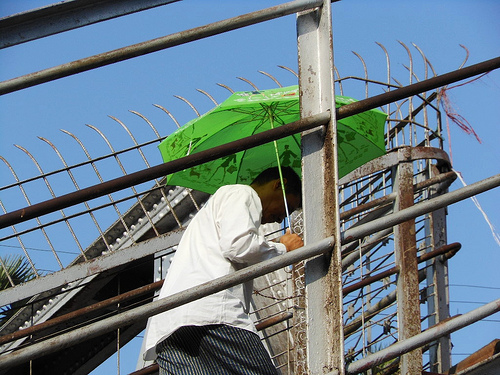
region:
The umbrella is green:
[187, 78, 287, 182]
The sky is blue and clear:
[74, 14, 204, 129]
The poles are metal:
[316, 94, 438, 301]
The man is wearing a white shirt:
[150, 181, 294, 368]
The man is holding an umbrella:
[253, 150, 320, 287]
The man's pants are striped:
[174, 322, 241, 373]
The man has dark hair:
[239, 158, 320, 248]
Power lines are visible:
[433, 182, 496, 339]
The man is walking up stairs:
[90, 155, 311, 357]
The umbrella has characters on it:
[181, 114, 370, 230]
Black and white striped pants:
[155, 319, 285, 374]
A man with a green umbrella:
[159, 81, 390, 198]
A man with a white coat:
[140, 179, 291, 363]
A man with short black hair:
[255, 162, 307, 210]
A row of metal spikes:
[0, 35, 471, 292]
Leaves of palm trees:
[0, 252, 54, 330]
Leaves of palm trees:
[346, 340, 446, 374]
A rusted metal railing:
[0, 144, 462, 374]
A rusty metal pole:
[0, 55, 498, 233]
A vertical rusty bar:
[295, 2, 347, 374]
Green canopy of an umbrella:
[158, 85, 383, 204]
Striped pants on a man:
[154, 320, 281, 372]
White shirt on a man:
[141, 185, 282, 334]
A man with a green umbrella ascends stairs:
[143, 85, 397, 373]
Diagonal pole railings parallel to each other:
[3, 10, 498, 373]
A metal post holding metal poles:
[390, 153, 423, 374]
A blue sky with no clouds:
[2, 4, 498, 322]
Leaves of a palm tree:
[0, 255, 62, 304]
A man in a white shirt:
[141, 165, 306, 373]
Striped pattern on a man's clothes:
[165, 343, 261, 373]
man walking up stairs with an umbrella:
[135, 87, 389, 374]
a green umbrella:
[160, 87, 389, 249]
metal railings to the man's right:
[1, 6, 498, 373]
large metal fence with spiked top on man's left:
[0, 44, 448, 374]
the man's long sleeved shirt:
[142, 184, 302, 357]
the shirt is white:
[131, 183, 287, 355]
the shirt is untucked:
[144, 181, 291, 360]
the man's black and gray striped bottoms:
[158, 325, 280, 373]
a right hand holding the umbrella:
[279, 230, 304, 255]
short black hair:
[251, 167, 301, 203]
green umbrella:
[148, 76, 385, 166]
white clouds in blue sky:
[364, 36, 394, 81]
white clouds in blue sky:
[37, 89, 72, 116]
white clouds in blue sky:
[42, 96, 93, 143]